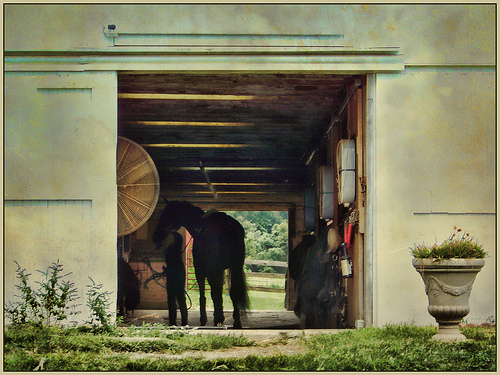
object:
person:
[157, 224, 186, 330]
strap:
[180, 236, 192, 253]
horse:
[149, 199, 249, 331]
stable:
[0, 0, 498, 335]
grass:
[0, 324, 497, 374]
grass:
[408, 226, 487, 259]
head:
[151, 198, 184, 242]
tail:
[228, 227, 253, 316]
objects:
[325, 225, 342, 252]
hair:
[225, 226, 251, 306]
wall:
[372, 67, 495, 324]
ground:
[1, 323, 500, 375]